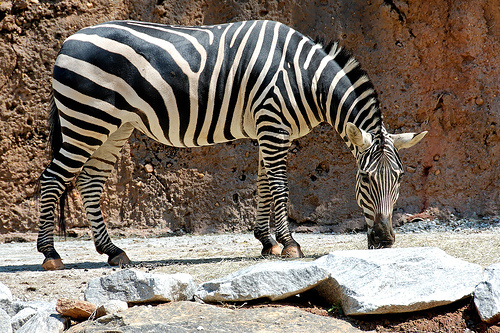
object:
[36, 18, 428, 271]
zebra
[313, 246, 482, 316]
rocks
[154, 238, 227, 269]
dirt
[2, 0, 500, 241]
wall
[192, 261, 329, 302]
stone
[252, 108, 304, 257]
legs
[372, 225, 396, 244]
nose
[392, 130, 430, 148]
ear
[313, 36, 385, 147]
mane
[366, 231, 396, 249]
eat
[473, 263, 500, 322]
rock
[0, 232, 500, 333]
ground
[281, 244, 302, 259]
hooves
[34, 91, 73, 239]
tail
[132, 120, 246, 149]
belly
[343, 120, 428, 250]
headdown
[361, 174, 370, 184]
eye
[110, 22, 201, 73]
spot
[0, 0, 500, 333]
zoo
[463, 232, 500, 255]
grass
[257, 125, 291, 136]
stripes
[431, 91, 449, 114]
holes